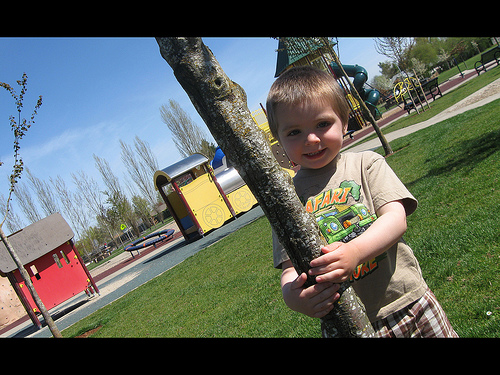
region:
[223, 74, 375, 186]
head of the kid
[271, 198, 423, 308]
arms of the kid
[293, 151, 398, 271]
shirt on the kid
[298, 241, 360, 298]
hand of the kid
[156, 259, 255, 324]
green grass in photo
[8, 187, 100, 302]
red building in the background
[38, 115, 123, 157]
sky above the land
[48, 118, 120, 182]
clouds in the sky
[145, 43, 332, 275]
tree next to the kid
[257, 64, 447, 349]
little boy hugging a tree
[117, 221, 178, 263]
trampoline near the train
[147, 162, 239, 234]
yellow train play toy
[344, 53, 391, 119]
slide on the playground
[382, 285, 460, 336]
plaid shorts on the boy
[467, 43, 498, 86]
bench in the park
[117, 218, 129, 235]
sign in the park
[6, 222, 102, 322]
red play house in the park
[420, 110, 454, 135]
path in the park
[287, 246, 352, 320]
hands on the tree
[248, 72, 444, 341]
Young boy holding a tree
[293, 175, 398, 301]
Boy is wearing shirt that says Safari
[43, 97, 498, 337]
Grass behind young boy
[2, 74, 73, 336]
Small tree in the midst of grassy field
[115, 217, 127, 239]
Black and yellow sign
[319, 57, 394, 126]
Green enclosed slide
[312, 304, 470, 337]
Boy is wearing plaid shorts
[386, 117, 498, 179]
Shadow of a tree on the ground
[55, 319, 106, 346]
Mulch around the tree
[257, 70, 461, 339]
Little boy gripping a tree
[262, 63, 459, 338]
Little boy smiling for the camera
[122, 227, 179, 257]
Blue trampoline with two short legs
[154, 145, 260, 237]
Yellow train on a children's playground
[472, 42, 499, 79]
Park bench on a playground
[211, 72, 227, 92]
Hole in a small tree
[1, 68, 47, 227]
Leaves on a tree branch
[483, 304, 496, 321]
Lonely flower in the grass